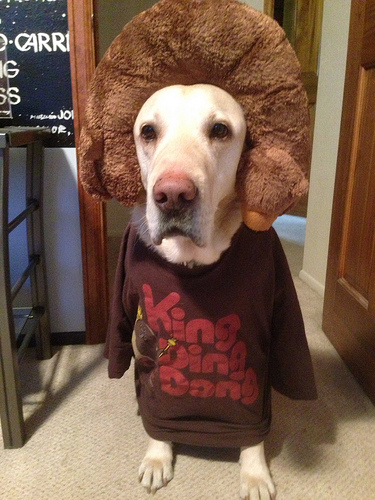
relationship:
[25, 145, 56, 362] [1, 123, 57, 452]
legs on table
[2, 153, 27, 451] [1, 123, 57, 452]
legs on table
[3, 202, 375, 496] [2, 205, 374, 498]
carpet on floor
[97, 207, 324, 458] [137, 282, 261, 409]
shirt with writing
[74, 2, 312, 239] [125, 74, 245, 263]
object on head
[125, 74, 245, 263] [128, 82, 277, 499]
head of creature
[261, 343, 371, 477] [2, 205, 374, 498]
shadow on floor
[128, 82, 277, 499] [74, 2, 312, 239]
creature wearing object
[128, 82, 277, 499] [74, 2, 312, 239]
creature in object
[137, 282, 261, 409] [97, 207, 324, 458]
writing on shirt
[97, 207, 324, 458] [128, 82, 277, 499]
shirt on creature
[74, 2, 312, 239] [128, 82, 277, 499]
object on creature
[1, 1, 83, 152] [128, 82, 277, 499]
sign behind creature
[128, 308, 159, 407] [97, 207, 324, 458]
creature on shirt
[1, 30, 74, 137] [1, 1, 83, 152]
writing on sign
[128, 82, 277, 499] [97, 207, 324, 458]
creature in shirt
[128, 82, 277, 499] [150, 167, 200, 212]
creature has nose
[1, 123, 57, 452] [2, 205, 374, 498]
table on floor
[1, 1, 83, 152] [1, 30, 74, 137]
sign with writing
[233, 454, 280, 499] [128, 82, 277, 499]
paws of creature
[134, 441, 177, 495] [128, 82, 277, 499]
paws of creature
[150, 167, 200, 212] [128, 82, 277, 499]
nose on creature